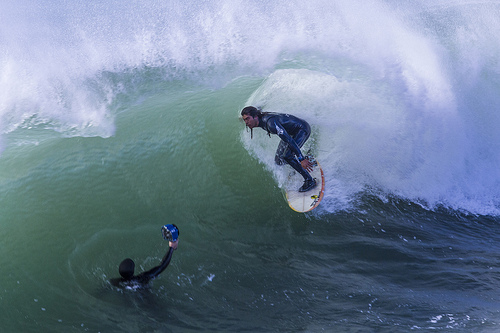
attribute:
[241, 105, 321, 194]
man — surfing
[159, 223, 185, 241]
camera — blue, waterproof, large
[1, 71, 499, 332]
water — green, blue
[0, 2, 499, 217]
splash — white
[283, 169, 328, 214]
surfboard — white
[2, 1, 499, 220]
wave — crashing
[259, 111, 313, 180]
wetsuit — black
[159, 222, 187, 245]
helmet — blue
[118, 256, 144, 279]
hair — black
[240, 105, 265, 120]
hair — long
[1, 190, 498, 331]
water — dark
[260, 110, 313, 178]
suit — blue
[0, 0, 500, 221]
waves — crashing